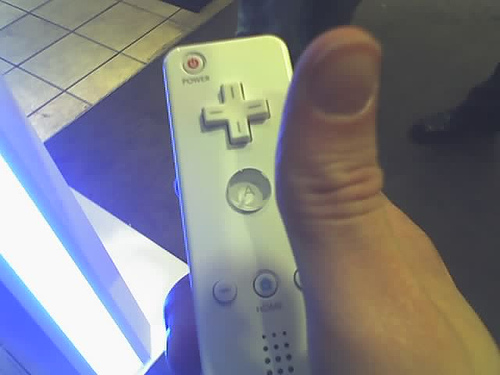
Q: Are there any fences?
A: No, there are no fences.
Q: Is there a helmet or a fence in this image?
A: No, there are no fences or helmets.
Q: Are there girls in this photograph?
A: No, there are no girls.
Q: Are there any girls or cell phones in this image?
A: No, there are no girls or cell phones.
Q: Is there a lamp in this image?
A: No, there are no lamps.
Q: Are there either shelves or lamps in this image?
A: No, there are no lamps or shelves.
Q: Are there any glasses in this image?
A: No, there are no glasses.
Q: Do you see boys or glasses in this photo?
A: No, there are no glasses or boys.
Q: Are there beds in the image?
A: No, there are no beds.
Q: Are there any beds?
A: No, there are no beds.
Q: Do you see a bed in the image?
A: No, there are no beds.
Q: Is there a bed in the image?
A: No, there are no beds.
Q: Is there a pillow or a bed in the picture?
A: No, there are no beds or pillows.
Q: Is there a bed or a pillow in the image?
A: No, there are no beds or pillows.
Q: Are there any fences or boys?
A: No, there are no fences or boys.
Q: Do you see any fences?
A: No, there are no fences.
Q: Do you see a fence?
A: No, there are no fences.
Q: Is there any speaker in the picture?
A: Yes, there is a speaker.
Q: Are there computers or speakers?
A: Yes, there is a speaker.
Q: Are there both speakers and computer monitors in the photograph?
A: No, there is a speaker but no computer monitors.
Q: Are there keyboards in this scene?
A: No, there are no keyboards.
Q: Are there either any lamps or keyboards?
A: No, there are no keyboards or lamps.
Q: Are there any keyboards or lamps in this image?
A: No, there are no keyboards or lamps.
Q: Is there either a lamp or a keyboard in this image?
A: No, there are no keyboards or lamps.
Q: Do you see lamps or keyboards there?
A: No, there are no keyboards or lamps.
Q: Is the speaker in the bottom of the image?
A: Yes, the speaker is in the bottom of the image.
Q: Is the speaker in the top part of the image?
A: No, the speaker is in the bottom of the image.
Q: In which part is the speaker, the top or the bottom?
A: The speaker is in the bottom of the image.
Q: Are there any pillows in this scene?
A: No, there are no pillows.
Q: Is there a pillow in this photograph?
A: No, there are no pillows.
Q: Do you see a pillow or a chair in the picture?
A: No, there are no pillows or chairs.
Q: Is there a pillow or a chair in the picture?
A: No, there are no pillows or chairs.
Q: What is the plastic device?
A: The device is a controller.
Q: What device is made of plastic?
A: The device is a controller.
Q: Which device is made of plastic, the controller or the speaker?
A: The controller is made of plastic.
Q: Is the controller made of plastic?
A: Yes, the controller is made of plastic.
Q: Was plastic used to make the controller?
A: Yes, the controller is made of plastic.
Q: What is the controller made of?
A: The controller is made of plastic.